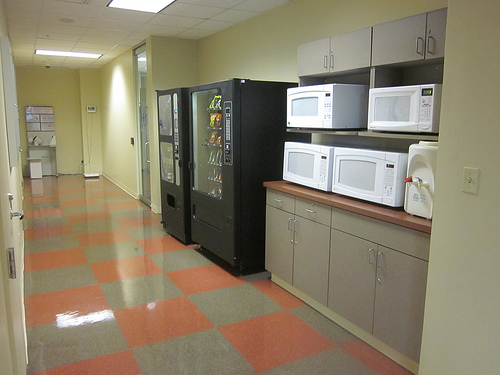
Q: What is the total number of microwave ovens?
A: 4.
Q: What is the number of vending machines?
A: 2.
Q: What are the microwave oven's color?
A: White.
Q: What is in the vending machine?
A: Snacks.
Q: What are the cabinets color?
A: Gray.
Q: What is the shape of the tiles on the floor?
A: Square.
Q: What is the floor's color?
A: Orange and Grey.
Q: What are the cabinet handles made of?
A: Metal.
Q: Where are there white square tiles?
A: Ceiling.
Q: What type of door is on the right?
A: Clear door.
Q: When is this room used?
A: Lunch breaks.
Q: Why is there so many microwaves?
A: Lots of employees.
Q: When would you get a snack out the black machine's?
A: After putting in money.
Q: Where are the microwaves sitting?
A: On shelves.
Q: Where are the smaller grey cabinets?
A: Above microwave.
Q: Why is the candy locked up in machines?
A: Candy is not free.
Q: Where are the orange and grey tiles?
A: Floor.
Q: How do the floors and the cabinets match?
A: Grey color.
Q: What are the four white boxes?
A: Microwave ovens.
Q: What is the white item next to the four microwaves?
A: A water dispenser.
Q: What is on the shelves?
A: Microwaves.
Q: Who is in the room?
A: No one.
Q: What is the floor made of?
A: Tiles.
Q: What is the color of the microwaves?
A: White.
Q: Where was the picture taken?
A: In the kitchen at an office.